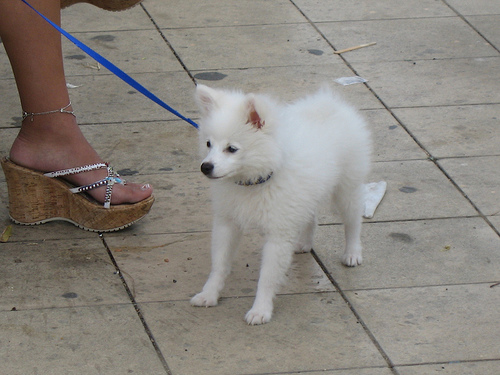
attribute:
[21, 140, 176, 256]
sandal — platform type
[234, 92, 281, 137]
ear — dog's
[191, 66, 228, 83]
spot — black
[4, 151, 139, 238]
sandal — multi colored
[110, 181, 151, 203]
toe — big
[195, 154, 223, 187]
nose — black